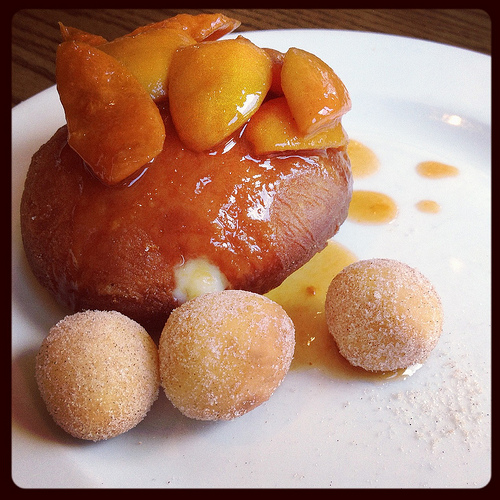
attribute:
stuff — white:
[168, 255, 223, 300]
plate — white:
[375, 42, 462, 138]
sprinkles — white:
[336, 369, 484, 478]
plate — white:
[11, 25, 492, 488]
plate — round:
[352, 23, 486, 145]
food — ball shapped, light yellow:
[30, 303, 162, 454]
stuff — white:
[179, 268, 221, 296]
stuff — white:
[179, 267, 222, 301]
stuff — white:
[181, 259, 221, 298]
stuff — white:
[180, 266, 216, 301]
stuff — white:
[174, 263, 222, 301]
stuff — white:
[177, 262, 227, 298]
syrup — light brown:
[290, 280, 324, 313]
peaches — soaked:
[52, 13, 354, 181]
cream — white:
[183, 265, 221, 295]